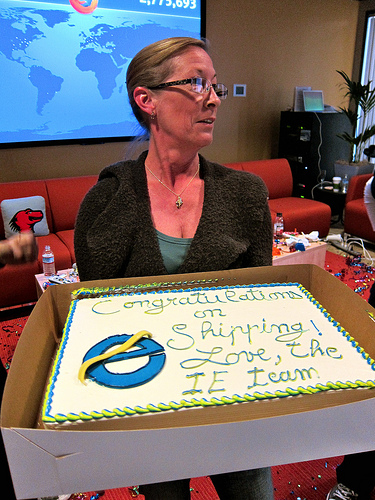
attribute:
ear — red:
[129, 85, 156, 118]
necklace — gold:
[127, 135, 214, 220]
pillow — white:
[1, 188, 62, 244]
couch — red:
[150, 124, 352, 247]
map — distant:
[2, 10, 207, 124]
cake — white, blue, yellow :
[52, 267, 363, 427]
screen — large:
[2, 2, 222, 147]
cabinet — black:
[269, 87, 361, 209]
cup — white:
[318, 165, 347, 192]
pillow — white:
[0, 181, 56, 247]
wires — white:
[312, 220, 357, 266]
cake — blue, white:
[46, 255, 357, 410]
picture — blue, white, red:
[0, 4, 216, 135]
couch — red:
[190, 143, 357, 249]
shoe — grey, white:
[312, 466, 363, 497]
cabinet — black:
[281, 97, 362, 215]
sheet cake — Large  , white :
[35, 278, 373, 419]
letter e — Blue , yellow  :
[74, 324, 170, 392]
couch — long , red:
[0, 158, 339, 298]